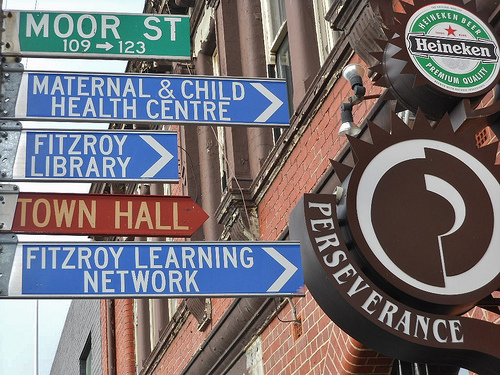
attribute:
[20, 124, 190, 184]
sign — blue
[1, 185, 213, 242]
sign — tan, red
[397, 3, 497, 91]
sign — Heineken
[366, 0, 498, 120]
sign — green, Heineken, beer, white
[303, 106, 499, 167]
spikes — brown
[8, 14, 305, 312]
signs — street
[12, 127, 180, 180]
blue sign — white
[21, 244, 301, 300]
sign — blue, white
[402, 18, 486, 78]
sign — round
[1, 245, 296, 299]
sign — Fitzroy Learning Network, blue, white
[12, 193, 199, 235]
sign — red, metal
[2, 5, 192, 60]
sign — green, white, street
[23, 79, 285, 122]
sign — steel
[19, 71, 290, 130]
sign — child, maternal, health center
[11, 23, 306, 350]
signs — all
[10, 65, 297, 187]
signs — blue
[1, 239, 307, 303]
sign — white, blue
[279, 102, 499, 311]
sign — white, brown, round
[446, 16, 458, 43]
star — red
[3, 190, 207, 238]
sign — red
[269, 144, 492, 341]
sign — fancy, white, brown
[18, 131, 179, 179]
sign — metal, blue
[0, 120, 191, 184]
sign — Fitzroy Library, blue, white